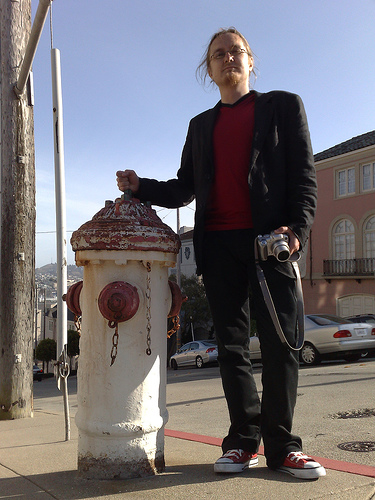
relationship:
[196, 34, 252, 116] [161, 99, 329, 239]
man wearing coat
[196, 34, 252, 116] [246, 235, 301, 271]
man with camera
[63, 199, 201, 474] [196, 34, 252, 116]
hydrant beside man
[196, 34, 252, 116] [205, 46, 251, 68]
man wearing eyeglasses